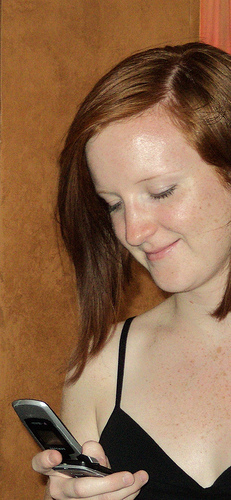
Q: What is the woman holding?
A: A phone.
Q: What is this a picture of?
A: A woman.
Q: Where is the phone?
A: In her hand.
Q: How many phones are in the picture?
A: One.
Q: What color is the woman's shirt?
A: Black.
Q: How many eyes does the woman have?
A: Two.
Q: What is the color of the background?
A: Brown.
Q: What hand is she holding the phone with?
A: Right hand.